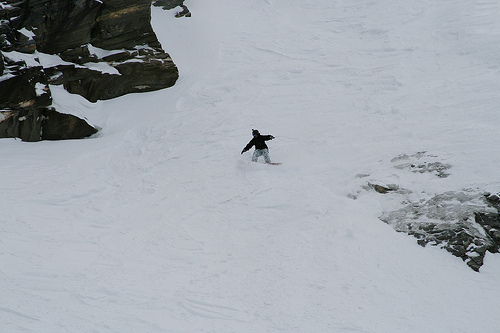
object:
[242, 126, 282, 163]
person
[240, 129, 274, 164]
bad image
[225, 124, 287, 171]
person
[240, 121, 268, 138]
hat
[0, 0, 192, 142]
rock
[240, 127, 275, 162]
person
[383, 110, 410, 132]
ground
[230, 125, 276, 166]
person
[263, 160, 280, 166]
snowboard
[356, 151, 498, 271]
ice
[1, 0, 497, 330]
rock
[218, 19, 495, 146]
ground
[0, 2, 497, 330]
mountain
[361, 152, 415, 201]
ground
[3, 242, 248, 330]
snow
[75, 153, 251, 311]
snow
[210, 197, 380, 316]
snow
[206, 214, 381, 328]
snow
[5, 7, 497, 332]
mountain side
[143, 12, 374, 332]
snow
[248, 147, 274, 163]
pants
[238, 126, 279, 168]
man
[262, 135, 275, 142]
arm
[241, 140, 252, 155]
arm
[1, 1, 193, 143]
rocks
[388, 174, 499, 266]
ice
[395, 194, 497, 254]
rocks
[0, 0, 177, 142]
rocks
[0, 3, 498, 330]
snow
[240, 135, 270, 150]
jacket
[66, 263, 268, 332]
snow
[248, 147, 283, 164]
snowboard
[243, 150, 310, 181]
snow board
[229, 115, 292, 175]
person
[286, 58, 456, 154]
snow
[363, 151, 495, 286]
mountain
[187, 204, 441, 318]
ground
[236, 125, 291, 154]
jacket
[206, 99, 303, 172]
person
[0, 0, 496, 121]
background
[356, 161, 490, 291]
rock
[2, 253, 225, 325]
tracks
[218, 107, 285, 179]
man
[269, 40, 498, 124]
ground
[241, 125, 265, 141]
black hat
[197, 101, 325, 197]
person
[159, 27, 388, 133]
snow